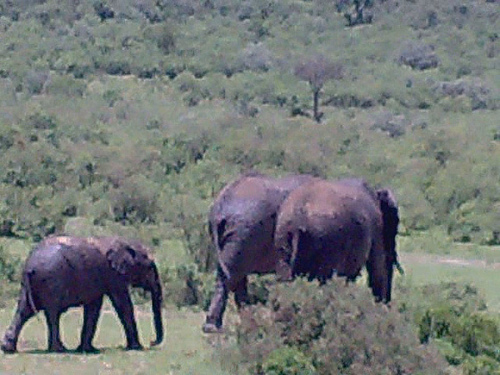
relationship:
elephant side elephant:
[191, 159, 411, 345] [191, 159, 411, 345]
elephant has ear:
[28, 229, 183, 349] [99, 253, 134, 277]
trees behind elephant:
[1, 3, 474, 250] [276, 177, 408, 316]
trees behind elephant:
[1, 3, 474, 250] [202, 171, 338, 334]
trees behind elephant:
[1, 3, 474, 250] [28, 229, 183, 349]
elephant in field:
[191, 159, 411, 345] [0, 2, 498, 372]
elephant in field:
[28, 229, 183, 349] [0, 2, 498, 372]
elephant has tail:
[191, 159, 411, 345] [207, 216, 234, 281]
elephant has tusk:
[191, 159, 411, 345] [393, 260, 410, 275]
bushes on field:
[0, 0, 500, 375] [0, 2, 498, 372]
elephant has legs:
[28, 229, 183, 349] [2, 298, 147, 355]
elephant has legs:
[191, 159, 411, 345] [203, 265, 404, 333]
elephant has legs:
[191, 159, 411, 345] [200, 259, 251, 335]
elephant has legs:
[28, 229, 183, 349] [1, 290, 73, 357]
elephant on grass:
[191, 159, 411, 345] [4, 2, 496, 373]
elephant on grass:
[28, 229, 183, 349] [4, 2, 496, 373]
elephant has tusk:
[191, 159, 411, 345] [390, 249, 405, 283]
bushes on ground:
[355, 40, 463, 128] [6, 2, 498, 367]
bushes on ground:
[0, 0, 500, 375] [6, 2, 498, 367]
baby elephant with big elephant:
[2, 235, 163, 351] [274, 178, 404, 306]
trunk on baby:
[144, 280, 165, 347] [1, 228, 167, 360]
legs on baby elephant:
[34, 297, 156, 347] [24, 230, 178, 342]